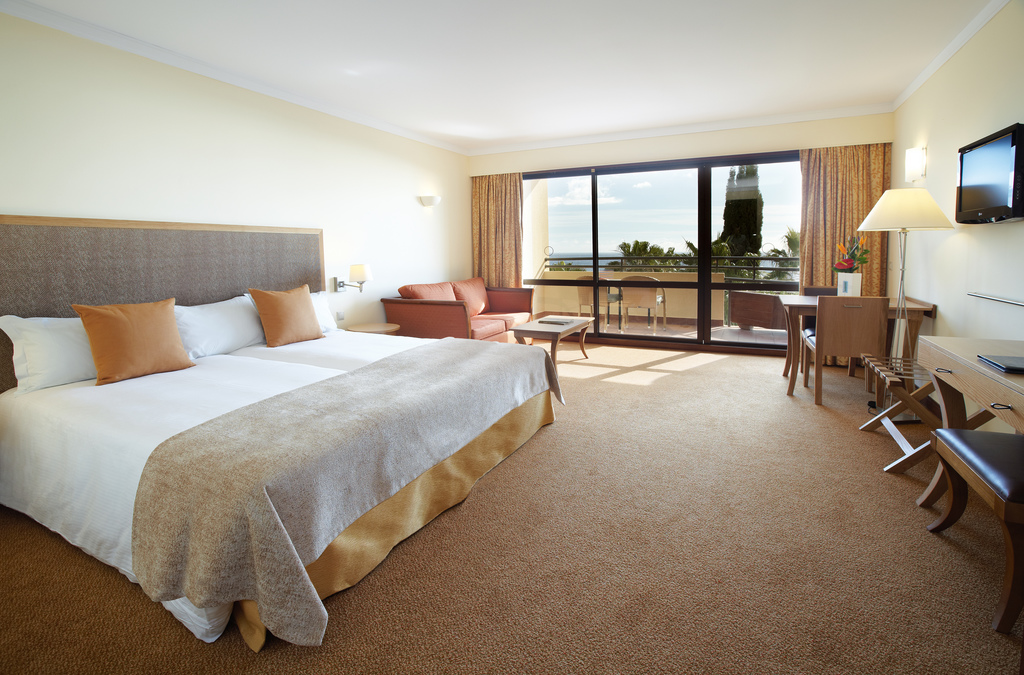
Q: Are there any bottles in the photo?
A: No, there are no bottles.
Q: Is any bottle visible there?
A: No, there are no bottles.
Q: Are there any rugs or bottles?
A: No, there are no bottles or rugs.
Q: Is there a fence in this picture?
A: No, there are no fences.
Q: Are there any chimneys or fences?
A: No, there are no fences or chimneys.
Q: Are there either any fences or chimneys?
A: No, there are no fences or chimneys.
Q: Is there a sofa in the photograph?
A: Yes, there is a sofa.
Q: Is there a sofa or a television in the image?
A: Yes, there is a sofa.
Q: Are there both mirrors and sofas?
A: No, there is a sofa but no mirrors.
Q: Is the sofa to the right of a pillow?
A: Yes, the sofa is to the right of a pillow.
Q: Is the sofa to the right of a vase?
A: No, the sofa is to the right of a pillow.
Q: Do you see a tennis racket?
A: No, there are no rackets.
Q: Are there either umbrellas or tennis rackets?
A: No, there are no tennis rackets or umbrellas.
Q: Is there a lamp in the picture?
A: Yes, there is a lamp.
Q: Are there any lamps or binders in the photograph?
A: Yes, there is a lamp.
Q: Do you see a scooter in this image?
A: No, there are no scooters.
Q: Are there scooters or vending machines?
A: No, there are no scooters or vending machines.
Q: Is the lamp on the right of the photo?
A: Yes, the lamp is on the right of the image.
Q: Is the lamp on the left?
A: No, the lamp is on the right of the image.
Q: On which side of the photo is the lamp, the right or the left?
A: The lamp is on the right of the image.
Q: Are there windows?
A: Yes, there is a window.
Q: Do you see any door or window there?
A: Yes, there is a window.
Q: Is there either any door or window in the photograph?
A: Yes, there is a window.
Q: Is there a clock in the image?
A: No, there are no clocks.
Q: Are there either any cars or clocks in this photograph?
A: No, there are no clocks or cars.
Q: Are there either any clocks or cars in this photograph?
A: No, there are no clocks or cars.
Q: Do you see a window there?
A: Yes, there is a window.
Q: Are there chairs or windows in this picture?
A: Yes, there is a window.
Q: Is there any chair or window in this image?
A: Yes, there is a window.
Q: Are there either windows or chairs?
A: Yes, there is a window.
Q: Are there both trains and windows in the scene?
A: No, there is a window but no trains.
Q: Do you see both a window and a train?
A: No, there is a window but no trains.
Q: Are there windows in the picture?
A: Yes, there is a window.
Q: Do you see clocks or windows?
A: Yes, there is a window.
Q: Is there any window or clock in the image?
A: Yes, there is a window.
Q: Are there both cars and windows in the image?
A: No, there is a window but no cars.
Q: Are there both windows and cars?
A: No, there is a window but no cars.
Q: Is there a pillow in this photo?
A: Yes, there is a pillow.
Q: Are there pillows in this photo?
A: Yes, there is a pillow.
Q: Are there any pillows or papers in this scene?
A: Yes, there is a pillow.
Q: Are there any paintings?
A: No, there are no paintings.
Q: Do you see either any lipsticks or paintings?
A: No, there are no paintings or lipsticks.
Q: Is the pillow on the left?
A: Yes, the pillow is on the left of the image.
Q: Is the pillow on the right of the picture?
A: No, the pillow is on the left of the image.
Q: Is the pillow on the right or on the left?
A: The pillow is on the left of the image.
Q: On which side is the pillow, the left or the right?
A: The pillow is on the left of the image.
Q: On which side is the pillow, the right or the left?
A: The pillow is on the left of the image.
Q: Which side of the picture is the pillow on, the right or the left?
A: The pillow is on the left of the image.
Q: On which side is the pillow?
A: The pillow is on the left of the image.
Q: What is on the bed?
A: The pillow is on the bed.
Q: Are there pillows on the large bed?
A: Yes, there is a pillow on the bed.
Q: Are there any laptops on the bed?
A: No, there is a pillow on the bed.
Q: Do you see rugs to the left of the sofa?
A: No, there is a pillow to the left of the sofa.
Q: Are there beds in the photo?
A: Yes, there is a bed.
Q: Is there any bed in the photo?
A: Yes, there is a bed.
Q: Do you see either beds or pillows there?
A: Yes, there is a bed.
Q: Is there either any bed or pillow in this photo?
A: Yes, there is a bed.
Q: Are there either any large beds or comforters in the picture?
A: Yes, there is a large bed.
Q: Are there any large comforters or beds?
A: Yes, there is a large bed.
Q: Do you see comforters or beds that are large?
A: Yes, the bed is large.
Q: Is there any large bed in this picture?
A: Yes, there is a large bed.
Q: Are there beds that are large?
A: Yes, there is a bed that is large.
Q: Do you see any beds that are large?
A: Yes, there is a bed that is large.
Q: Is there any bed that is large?
A: Yes, there is a bed that is large.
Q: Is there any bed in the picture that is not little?
A: Yes, there is a large bed.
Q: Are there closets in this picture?
A: No, there are no closets.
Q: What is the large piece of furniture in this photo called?
A: The piece of furniture is a bed.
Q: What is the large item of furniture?
A: The piece of furniture is a bed.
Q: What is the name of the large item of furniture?
A: The piece of furniture is a bed.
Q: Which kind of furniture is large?
A: The furniture is a bed.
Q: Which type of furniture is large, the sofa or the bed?
A: The bed is large.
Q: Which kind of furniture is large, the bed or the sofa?
A: The bed is large.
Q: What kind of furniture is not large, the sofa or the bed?
A: The sofa is not large.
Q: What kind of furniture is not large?
A: The furniture is a sofa.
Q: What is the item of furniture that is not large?
A: The piece of furniture is a sofa.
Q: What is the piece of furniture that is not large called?
A: The piece of furniture is a sofa.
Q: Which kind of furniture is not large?
A: The furniture is a sofa.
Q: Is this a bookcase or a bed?
A: This is a bed.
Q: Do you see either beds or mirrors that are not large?
A: No, there is a bed but it is large.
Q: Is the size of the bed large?
A: Yes, the bed is large.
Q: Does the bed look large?
A: Yes, the bed is large.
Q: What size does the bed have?
A: The bed has large size.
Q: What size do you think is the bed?
A: The bed is large.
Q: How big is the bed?
A: The bed is large.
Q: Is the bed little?
A: No, the bed is large.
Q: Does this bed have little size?
A: No, the bed is large.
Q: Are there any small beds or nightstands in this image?
A: No, there is a bed but it is large.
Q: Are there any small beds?
A: No, there is a bed but it is large.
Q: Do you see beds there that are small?
A: No, there is a bed but it is large.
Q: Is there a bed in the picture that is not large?
A: No, there is a bed but it is large.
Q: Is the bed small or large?
A: The bed is large.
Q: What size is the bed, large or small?
A: The bed is large.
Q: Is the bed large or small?
A: The bed is large.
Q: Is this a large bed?
A: Yes, this is a large bed.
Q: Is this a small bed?
A: No, this is a large bed.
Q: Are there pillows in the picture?
A: Yes, there is a pillow.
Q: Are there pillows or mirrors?
A: Yes, there is a pillow.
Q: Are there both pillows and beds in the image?
A: Yes, there are both a pillow and a bed.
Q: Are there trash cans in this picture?
A: No, there are no trash cans.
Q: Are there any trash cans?
A: No, there are no trash cans.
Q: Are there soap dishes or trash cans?
A: No, there are no trash cans or soap dishes.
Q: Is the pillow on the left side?
A: Yes, the pillow is on the left of the image.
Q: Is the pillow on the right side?
A: No, the pillow is on the left of the image.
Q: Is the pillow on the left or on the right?
A: The pillow is on the left of the image.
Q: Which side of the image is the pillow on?
A: The pillow is on the left of the image.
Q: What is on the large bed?
A: The pillow is on the bed.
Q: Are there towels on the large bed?
A: No, there is a pillow on the bed.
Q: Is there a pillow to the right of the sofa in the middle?
A: No, the pillow is to the left of the sofa.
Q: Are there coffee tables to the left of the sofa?
A: No, there is a pillow to the left of the sofa.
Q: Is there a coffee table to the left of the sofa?
A: No, there is a pillow to the left of the sofa.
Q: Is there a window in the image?
A: Yes, there are windows.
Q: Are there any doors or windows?
A: Yes, there are windows.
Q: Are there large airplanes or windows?
A: Yes, there are large windows.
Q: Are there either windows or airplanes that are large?
A: Yes, the windows are large.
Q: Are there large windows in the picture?
A: Yes, there are large windows.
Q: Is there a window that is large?
A: Yes, there are windows that are large.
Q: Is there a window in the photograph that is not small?
A: Yes, there are large windows.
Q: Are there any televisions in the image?
A: Yes, there is a television.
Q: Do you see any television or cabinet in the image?
A: Yes, there is a television.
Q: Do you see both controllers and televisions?
A: No, there is a television but no controllers.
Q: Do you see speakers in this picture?
A: No, there are no speakers.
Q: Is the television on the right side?
A: Yes, the television is on the right of the image.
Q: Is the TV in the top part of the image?
A: Yes, the TV is in the top of the image.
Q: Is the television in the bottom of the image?
A: No, the television is in the top of the image.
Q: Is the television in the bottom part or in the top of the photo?
A: The television is in the top of the image.